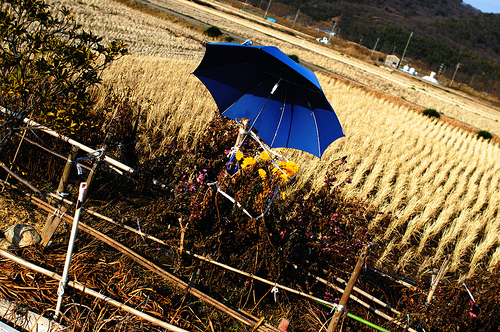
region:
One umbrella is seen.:
[203, 36, 329, 166]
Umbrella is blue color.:
[204, 43, 322, 168]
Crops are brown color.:
[372, 113, 445, 210]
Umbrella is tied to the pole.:
[222, 120, 265, 175]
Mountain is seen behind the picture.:
[365, 5, 495, 85]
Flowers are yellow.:
[236, 147, 296, 187]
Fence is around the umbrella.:
[18, 126, 479, 330]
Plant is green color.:
[14, 30, 75, 101]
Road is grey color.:
[149, 0, 201, 34]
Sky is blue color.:
[467, 0, 499, 14]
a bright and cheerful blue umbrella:
[191, 39, 349, 159]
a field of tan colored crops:
[13, 0, 498, 308]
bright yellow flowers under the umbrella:
[229, 139, 304, 215]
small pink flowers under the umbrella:
[170, 146, 231, 210]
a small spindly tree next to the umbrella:
[0, 3, 135, 145]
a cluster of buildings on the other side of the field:
[382, 43, 442, 88]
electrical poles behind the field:
[263, 7, 460, 92]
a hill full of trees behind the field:
[270, 1, 495, 127]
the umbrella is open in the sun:
[188, 38, 345, 232]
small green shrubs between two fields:
[195, 21, 495, 151]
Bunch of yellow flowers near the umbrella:
[233, 139, 299, 205]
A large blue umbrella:
[189, 34, 352, 161]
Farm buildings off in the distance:
[380, 49, 445, 86]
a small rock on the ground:
[2, 220, 43, 250]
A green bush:
[1, 0, 133, 144]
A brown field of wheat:
[326, 76, 499, 268]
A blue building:
[263, 15, 281, 23]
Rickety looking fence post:
[310, 234, 387, 330]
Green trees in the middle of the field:
[421, 105, 497, 144]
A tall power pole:
[396, 27, 415, 74]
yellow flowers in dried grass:
[220, 129, 311, 209]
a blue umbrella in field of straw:
[174, 18, 346, 160]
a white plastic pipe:
[56, 183, 80, 318]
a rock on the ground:
[1, 214, 41, 254]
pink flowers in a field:
[186, 168, 207, 231]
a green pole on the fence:
[340, 305, 380, 330]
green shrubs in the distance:
[423, 105, 495, 141]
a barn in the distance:
[386, 40, 401, 75]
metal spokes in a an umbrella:
[274, 108, 288, 133]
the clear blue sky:
[480, 3, 494, 14]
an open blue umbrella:
[182, 27, 346, 156]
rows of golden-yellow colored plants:
[350, 121, 479, 248]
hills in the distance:
[422, 0, 497, 56]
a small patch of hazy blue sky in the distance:
[475, 0, 495, 10]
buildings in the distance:
[375, 53, 438, 86]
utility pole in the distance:
[444, 57, 466, 89]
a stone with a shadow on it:
[1, 217, 39, 247]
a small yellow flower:
[233, 147, 243, 161]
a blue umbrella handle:
[226, 151, 239, 175]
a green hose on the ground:
[344, 307, 390, 330]